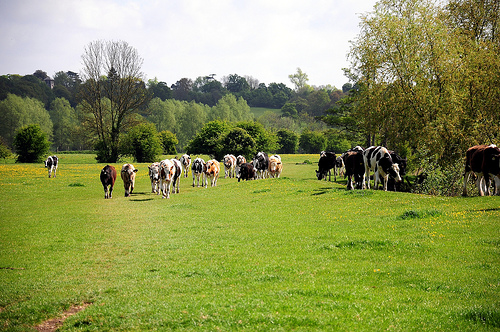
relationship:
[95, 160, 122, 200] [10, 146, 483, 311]
cow in field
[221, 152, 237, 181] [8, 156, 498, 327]
cow in field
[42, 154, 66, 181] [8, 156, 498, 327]
cow on field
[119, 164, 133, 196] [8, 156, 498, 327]
cow on field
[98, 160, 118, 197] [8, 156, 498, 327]
cow on field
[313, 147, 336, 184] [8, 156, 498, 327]
cow on field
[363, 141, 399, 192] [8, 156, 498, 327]
cow on field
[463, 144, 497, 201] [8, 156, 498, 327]
cow on field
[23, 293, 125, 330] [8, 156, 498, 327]
dirt in field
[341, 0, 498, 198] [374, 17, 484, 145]
tree covered in leaves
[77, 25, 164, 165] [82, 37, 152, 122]
tree without leaves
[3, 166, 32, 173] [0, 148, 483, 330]
flowers in pasture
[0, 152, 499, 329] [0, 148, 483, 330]
grass in pasture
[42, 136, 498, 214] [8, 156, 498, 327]
cows in field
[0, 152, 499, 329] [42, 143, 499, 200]
grass in front of cows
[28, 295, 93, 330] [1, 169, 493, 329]
bare patch in grass